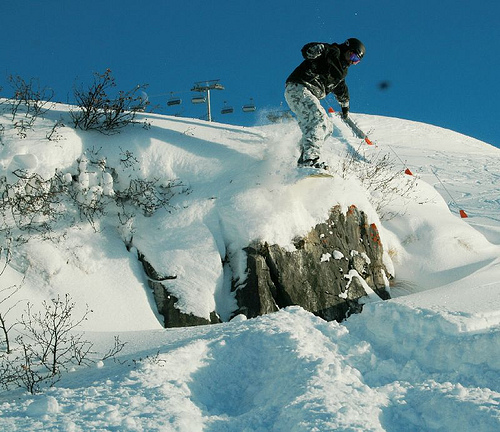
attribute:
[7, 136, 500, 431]
snow — on the ground, white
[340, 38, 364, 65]
helmet — black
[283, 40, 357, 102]
jacket — black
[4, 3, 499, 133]
top — blue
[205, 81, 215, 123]
pole — made of metal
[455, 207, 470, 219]
flag — orange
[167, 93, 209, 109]
empty — ski lift